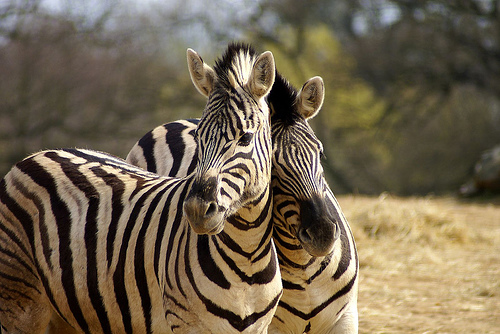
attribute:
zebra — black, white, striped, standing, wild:
[2, 41, 284, 332]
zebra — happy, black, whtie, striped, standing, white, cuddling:
[126, 67, 360, 334]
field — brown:
[333, 195, 499, 332]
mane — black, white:
[210, 38, 259, 108]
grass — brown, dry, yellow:
[334, 197, 499, 330]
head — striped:
[185, 46, 281, 237]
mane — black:
[265, 68, 304, 130]